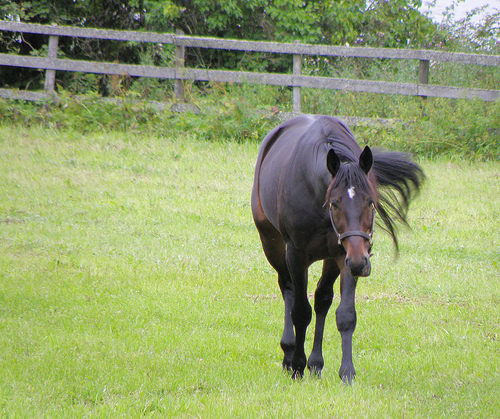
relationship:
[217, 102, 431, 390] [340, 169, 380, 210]
horse has a face with a white dot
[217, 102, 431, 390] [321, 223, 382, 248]
horse wearing harness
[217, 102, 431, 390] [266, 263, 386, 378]
horse with 4 legs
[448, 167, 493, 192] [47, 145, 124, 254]
grass in field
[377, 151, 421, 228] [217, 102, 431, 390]
tail of horse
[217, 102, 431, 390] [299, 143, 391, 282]
horse has head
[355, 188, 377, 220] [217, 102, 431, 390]
eye of horse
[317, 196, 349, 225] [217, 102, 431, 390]
eye of horse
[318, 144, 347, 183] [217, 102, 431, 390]
ear of horse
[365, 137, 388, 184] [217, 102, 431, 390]
ear of horse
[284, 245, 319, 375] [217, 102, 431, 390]
leg of horse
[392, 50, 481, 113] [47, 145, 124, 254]
fence in field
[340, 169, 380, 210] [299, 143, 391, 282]
white dot on head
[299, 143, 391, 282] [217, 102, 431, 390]
head on horse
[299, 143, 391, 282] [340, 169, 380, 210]
head has white dot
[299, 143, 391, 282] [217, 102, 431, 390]
head of horse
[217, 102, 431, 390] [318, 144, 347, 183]
horse has ear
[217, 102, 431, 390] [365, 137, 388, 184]
horse has ear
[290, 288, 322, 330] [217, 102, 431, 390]
knee of horse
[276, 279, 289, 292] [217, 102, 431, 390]
knee of horse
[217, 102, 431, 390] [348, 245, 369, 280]
horse has nose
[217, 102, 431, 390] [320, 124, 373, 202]
horse has mane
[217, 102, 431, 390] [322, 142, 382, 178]
horse with ears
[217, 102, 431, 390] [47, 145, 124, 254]
horse in field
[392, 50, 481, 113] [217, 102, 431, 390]
fence behind horse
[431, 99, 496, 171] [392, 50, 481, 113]
bush by fence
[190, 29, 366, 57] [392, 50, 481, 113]
rail of fence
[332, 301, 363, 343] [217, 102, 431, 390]
knee of horse